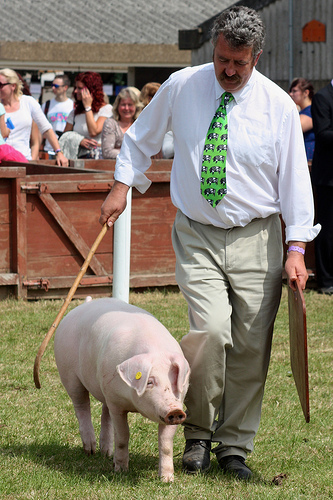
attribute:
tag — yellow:
[134, 372, 146, 379]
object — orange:
[301, 18, 326, 44]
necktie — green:
[172, 88, 247, 221]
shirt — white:
[113, 62, 322, 243]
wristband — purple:
[289, 242, 308, 258]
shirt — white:
[162, 72, 302, 257]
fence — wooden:
[3, 156, 179, 296]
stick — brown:
[83, 210, 103, 283]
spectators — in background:
[1, 62, 328, 167]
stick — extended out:
[32, 221, 109, 389]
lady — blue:
[0, 66, 68, 166]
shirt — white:
[0, 94, 53, 160]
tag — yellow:
[133, 370, 142, 380]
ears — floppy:
[113, 352, 191, 397]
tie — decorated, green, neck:
[200, 92, 234, 209]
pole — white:
[108, 162, 145, 308]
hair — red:
[78, 68, 110, 112]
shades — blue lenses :
[49, 82, 70, 89]